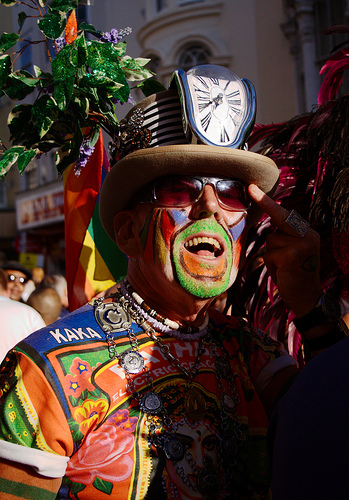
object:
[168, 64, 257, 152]
clock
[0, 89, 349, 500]
man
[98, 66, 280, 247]
top hat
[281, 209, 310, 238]
ring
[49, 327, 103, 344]
letters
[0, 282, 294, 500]
shirt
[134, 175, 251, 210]
glasses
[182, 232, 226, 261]
mouth